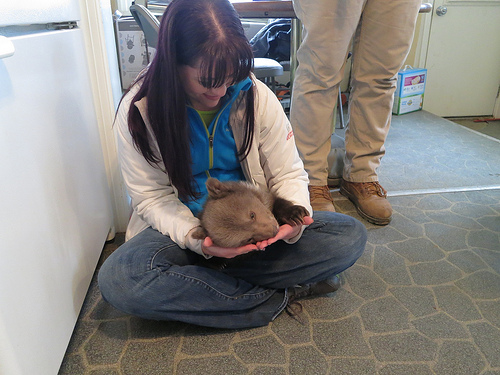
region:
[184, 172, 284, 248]
the head of an animal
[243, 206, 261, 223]
the eye of an animal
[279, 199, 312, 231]
the paw of an animal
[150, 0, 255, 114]
the head of a woman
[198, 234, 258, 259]
the hand of a woman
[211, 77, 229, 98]
the nose of a woman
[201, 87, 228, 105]
the mouth of a woman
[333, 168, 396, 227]
a brown boot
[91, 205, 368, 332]
a pair of blue jeans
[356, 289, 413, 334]
a stone in the floor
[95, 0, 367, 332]
woman holding bear cub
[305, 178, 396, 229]
brown work boots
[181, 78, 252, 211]
bright blue fleece with green zipper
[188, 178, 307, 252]
baby brown bear cub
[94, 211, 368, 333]
crossed legs in jeans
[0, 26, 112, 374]
bottom door of a refrigerator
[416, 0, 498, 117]
closed door in background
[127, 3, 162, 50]
top back of a chair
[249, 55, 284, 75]
front of a chair seat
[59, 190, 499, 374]
stone shaped tiled floor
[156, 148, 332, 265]
An animal is holding it's head in a girl's hands..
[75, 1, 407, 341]
A young girl is holding an animal.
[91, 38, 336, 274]
A girl is wearing a white jacket.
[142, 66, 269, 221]
A girl is wearing a blue and green top under a white jacket.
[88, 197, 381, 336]
A girl is wearing jeans.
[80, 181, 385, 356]
The color of a girl's jeans is blue.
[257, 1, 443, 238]
A person is standing next to a girl.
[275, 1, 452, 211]
A person is wearing tan pants.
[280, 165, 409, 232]
A person is wearing brown shoes.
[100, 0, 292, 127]
A chair is behind a girl.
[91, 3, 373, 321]
a little girl with a dog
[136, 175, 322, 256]
head of dog on hands of girl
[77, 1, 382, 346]
girl has a white coat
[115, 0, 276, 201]
girl has long black hair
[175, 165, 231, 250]
ears of dog are round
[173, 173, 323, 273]
head of dog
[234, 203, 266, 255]
open eyes of dog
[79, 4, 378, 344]
woman wears blue jeans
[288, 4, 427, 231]
person wearing tan shoes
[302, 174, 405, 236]
brown shoes with brown pins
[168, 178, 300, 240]
baby brown bear in arms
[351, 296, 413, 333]
grey pebbled floor with mortar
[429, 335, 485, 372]
grey pebbled floor with mortar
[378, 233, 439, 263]
grey pebbled floor with mortar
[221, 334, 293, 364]
grey pebbled floor with mortar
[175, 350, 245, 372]
grey pebbled floor with mortar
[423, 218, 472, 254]
grey pebbled floor with mortar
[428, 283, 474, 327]
grey pebbled floor with mortar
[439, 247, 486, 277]
grey pebbled floor with mortar